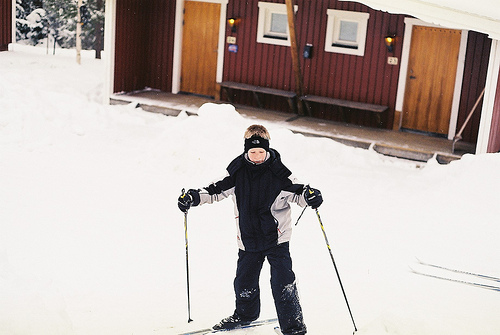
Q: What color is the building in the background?
A: Red.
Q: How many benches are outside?
A: Two.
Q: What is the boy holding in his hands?
A: Ski poles.